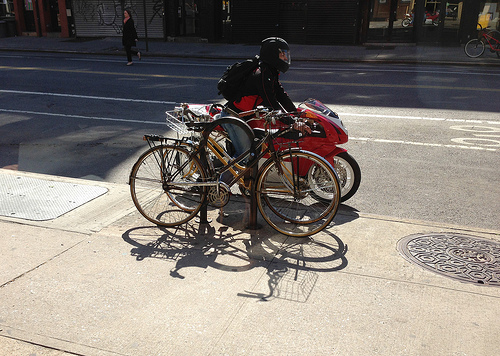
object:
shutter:
[72, 0, 169, 39]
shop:
[69, 0, 498, 46]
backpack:
[217, 57, 264, 102]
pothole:
[378, 213, 499, 253]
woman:
[121, 7, 143, 67]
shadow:
[125, 225, 332, 313]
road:
[12, 52, 139, 171]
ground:
[440, 145, 495, 197]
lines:
[1, 84, 498, 156]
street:
[1, 46, 498, 233]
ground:
[418, 150, 456, 195]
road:
[37, 107, 109, 182]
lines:
[1, 88, 148, 126]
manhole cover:
[401, 230, 500, 288]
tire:
[257, 150, 342, 237]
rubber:
[353, 155, 361, 200]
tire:
[127, 136, 211, 225]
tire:
[308, 146, 363, 205]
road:
[9, 42, 490, 354]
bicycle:
[129, 117, 341, 237]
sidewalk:
[0, 164, 498, 354]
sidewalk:
[1, 27, 498, 64]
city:
[1, 0, 498, 355]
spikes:
[129, 149, 198, 228]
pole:
[199, 116, 259, 231]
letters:
[438, 115, 497, 158]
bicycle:
[130, 114, 335, 225]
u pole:
[197, 115, 260, 232]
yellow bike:
[157, 110, 341, 225]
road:
[37, 64, 447, 213]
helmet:
[259, 37, 291, 74]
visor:
[278, 48, 292, 65]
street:
[4, 39, 193, 193]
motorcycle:
[170, 98, 362, 203]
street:
[1, 49, 204, 174]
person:
[208, 36, 306, 202]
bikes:
[127, 94, 363, 236]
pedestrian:
[119, 8, 144, 65]